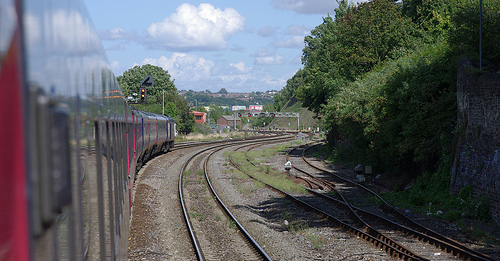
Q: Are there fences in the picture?
A: No, there are no fences.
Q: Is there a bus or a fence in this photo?
A: No, there are no fences or buses.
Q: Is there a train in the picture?
A: Yes, there is a train.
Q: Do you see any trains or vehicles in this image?
A: Yes, there is a train.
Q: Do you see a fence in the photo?
A: No, there are no fences.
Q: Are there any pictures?
A: No, there are no pictures.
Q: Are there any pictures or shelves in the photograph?
A: No, there are no pictures or shelves.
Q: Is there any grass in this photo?
A: Yes, there is grass.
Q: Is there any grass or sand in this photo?
A: Yes, there is grass.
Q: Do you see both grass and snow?
A: No, there is grass but no snow.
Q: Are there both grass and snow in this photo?
A: No, there is grass but no snow.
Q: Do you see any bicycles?
A: No, there are no bicycles.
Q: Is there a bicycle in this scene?
A: No, there are no bicycles.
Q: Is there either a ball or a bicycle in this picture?
A: No, there are no bicycles or balls.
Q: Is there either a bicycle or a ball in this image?
A: No, there are no bicycles or balls.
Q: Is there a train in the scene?
A: Yes, there is a train.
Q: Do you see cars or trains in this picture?
A: Yes, there is a train.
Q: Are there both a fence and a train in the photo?
A: No, there is a train but no fences.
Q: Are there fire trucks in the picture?
A: No, there are no fire trucks.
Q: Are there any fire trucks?
A: No, there are no fire trucks.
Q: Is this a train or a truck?
A: This is a train.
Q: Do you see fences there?
A: No, there are no fences.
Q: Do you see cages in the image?
A: No, there are no cages.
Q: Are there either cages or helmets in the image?
A: No, there are no cages or helmets.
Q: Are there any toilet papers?
A: No, there are no toilet papers.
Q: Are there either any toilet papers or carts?
A: No, there are no toilet papers or carts.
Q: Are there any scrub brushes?
A: No, there are no scrub brushes.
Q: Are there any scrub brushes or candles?
A: No, there are no scrub brushes or candles.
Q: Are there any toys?
A: No, there are no toys.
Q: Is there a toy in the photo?
A: No, there are no toys.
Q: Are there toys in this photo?
A: No, there are no toys.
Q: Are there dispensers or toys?
A: No, there are no toys or dispensers.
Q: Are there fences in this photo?
A: No, there are no fences.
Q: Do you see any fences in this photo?
A: No, there are no fences.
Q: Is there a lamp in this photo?
A: No, there are no lamps.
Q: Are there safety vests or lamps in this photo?
A: No, there are no lamps or safety vests.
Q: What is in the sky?
A: The clouds are in the sky.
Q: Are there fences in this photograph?
A: No, there are no fences.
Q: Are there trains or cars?
A: Yes, there is a train.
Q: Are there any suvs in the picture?
A: No, there are no suvs.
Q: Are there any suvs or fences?
A: No, there are no suvs or fences.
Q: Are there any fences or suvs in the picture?
A: No, there are no suvs or fences.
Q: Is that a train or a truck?
A: That is a train.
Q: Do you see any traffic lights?
A: Yes, there is a traffic light.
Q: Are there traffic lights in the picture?
A: Yes, there is a traffic light.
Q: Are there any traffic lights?
A: Yes, there is a traffic light.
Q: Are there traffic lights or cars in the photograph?
A: Yes, there is a traffic light.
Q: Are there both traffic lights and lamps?
A: No, there is a traffic light but no lamps.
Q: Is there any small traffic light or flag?
A: Yes, there is a small traffic light.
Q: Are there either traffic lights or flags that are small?
A: Yes, the traffic light is small.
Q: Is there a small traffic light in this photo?
A: Yes, there is a small traffic light.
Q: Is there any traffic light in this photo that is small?
A: Yes, there is a traffic light that is small.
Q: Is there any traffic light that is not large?
A: Yes, there is a small traffic light.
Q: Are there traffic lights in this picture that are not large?
A: Yes, there is a small traffic light.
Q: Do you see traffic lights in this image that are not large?
A: Yes, there is a small traffic light.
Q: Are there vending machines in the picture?
A: No, there are no vending machines.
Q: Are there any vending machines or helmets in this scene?
A: No, there are no vending machines or helmets.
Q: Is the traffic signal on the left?
A: Yes, the traffic signal is on the left of the image.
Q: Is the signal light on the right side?
A: No, the signal light is on the left of the image.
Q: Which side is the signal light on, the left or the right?
A: The signal light is on the left of the image.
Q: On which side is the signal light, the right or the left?
A: The signal light is on the left of the image.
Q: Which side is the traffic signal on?
A: The traffic signal is on the left of the image.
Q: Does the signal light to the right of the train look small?
A: Yes, the signal light is small.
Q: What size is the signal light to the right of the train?
A: The signal light is small.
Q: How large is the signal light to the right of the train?
A: The traffic signal is small.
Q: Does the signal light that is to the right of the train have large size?
A: No, the traffic light is small.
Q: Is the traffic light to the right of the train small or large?
A: The traffic signal is small.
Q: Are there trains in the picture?
A: Yes, there is a train.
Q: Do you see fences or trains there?
A: Yes, there is a train.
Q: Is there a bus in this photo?
A: No, there are no buses.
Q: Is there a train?
A: Yes, there is a train.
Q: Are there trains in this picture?
A: Yes, there is a train.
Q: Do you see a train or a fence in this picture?
A: Yes, there is a train.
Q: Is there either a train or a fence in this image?
A: Yes, there is a train.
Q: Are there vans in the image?
A: No, there are no vans.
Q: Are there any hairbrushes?
A: No, there are no hairbrushes.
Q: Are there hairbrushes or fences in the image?
A: No, there are no hairbrushes or fences.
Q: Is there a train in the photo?
A: Yes, there is a train.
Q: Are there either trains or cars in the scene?
A: Yes, there is a train.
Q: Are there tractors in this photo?
A: No, there are no tractors.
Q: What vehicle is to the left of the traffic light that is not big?
A: The vehicle is a train.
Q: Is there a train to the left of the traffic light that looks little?
A: Yes, there is a train to the left of the traffic light.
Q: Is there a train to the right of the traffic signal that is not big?
A: No, the train is to the left of the traffic light.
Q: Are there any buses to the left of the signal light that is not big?
A: No, there is a train to the left of the traffic light.